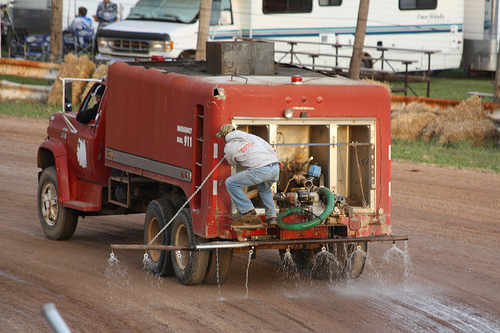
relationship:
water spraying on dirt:
[358, 239, 420, 272] [415, 216, 472, 311]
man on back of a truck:
[216, 123, 281, 225] [33, 24, 410, 299]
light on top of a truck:
[290, 71, 305, 86] [33, 24, 410, 299]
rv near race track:
[91, 5, 486, 79] [7, 108, 497, 332]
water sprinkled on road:
[101, 251, 137, 297] [1, 112, 498, 332]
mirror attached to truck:
[60, 79, 80, 116] [20, 58, 419, 240]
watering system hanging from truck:
[187, 229, 399, 261] [4, 115, 496, 331]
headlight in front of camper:
[145, 41, 170, 55] [109, 0, 462, 70]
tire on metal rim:
[34, 166, 77, 242] [39, 187, 59, 219]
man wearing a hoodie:
[213, 124, 278, 230] [223, 130, 278, 170]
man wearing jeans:
[216, 123, 281, 225] [221, 161, 285, 212]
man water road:
[216, 123, 281, 225] [1, 112, 498, 332]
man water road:
[54, 0, 101, 57] [1, 112, 498, 332]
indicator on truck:
[290, 64, 307, 87] [33, 24, 410, 299]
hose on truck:
[278, 191, 332, 231] [36, 74, 406, 273]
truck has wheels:
[33, 24, 410, 299] [127, 190, 237, 296]